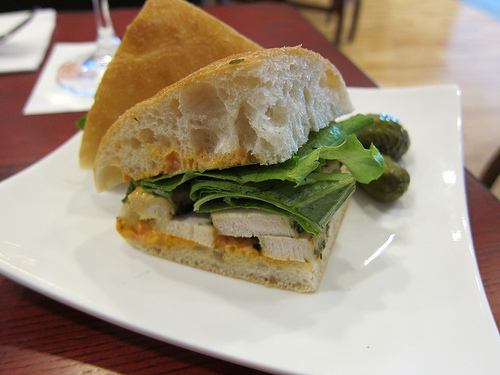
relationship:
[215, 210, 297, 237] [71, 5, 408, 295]
chicken on sandwich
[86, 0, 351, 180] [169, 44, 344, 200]
bread on sandwich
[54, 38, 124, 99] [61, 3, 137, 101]
bottom of wine glass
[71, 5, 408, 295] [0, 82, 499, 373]
sandwich on top of plate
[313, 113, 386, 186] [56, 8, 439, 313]
lettuce on sandwich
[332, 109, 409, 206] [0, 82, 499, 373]
pickles on side of plate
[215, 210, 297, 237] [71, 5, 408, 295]
chicken in sandwich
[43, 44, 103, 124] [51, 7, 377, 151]
napkin on table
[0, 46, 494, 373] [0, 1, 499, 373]
plate on table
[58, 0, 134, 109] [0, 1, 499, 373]
glass on table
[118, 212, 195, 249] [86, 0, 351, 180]
sauce on bread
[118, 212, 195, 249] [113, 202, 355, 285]
sauce on bread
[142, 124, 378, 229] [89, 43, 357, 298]
lettuce on sandwich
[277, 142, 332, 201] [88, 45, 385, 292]
lettuce on sandwich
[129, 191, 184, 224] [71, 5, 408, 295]
chicken on sandwich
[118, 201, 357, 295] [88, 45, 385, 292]
bread on sandwich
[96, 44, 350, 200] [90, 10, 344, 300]
bread on sandwich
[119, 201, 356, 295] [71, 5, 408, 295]
bread on sandwich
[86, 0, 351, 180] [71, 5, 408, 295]
bread on sandwich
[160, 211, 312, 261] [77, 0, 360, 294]
chicken in sandwich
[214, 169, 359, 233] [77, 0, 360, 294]
green leaf in sandwich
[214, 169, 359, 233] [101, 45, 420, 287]
green leaf in sandwich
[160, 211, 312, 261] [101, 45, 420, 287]
chicken in sandwich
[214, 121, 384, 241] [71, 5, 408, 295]
green leaf in sandwich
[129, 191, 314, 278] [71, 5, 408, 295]
chicken in sandwich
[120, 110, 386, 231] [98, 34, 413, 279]
leaf on sandwich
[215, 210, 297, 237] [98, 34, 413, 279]
chicken on sandwich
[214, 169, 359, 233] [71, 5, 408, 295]
green leaf on sandwich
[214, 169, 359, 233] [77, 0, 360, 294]
green leaf on sandwich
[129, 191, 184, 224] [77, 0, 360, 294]
chicken on sandwich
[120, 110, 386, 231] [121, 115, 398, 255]
leaf on sandwich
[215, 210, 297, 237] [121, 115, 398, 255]
chicken on sandwich